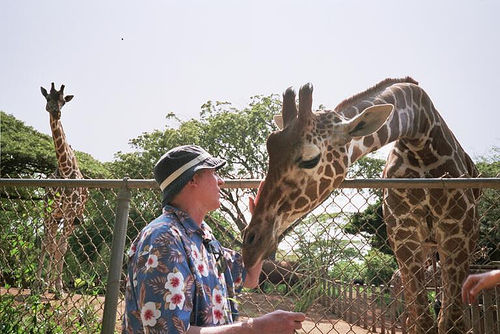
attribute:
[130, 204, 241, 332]
shirt — man's , flower 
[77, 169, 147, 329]
post — fence , metal 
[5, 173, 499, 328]
fence — link , chain 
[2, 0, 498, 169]
sky — clear 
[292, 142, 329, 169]
eye — black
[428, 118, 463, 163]
spot — Brown 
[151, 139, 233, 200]
hat — white , Blue 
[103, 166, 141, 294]
pole — long 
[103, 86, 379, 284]
tree — green , Tall 